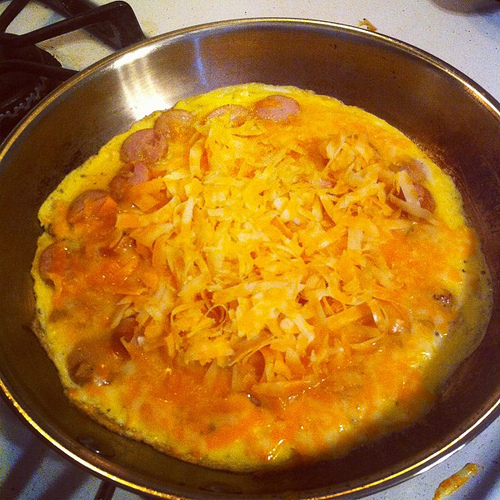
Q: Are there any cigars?
A: No, there are no cigars.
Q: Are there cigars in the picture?
A: No, there are no cigars.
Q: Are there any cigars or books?
A: No, there are no cigars or books.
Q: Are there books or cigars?
A: No, there are no cigars or books.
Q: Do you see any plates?
A: No, there are no plates.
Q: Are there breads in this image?
A: No, there are no breads.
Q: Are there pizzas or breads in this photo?
A: No, there are no breads or pizzas.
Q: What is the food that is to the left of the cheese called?
A: The food is a sausage.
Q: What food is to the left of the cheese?
A: The food is a sausage.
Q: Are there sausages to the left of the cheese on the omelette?
A: Yes, there is a sausage to the left of the cheese.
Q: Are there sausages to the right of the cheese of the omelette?
A: No, the sausage is to the left of the cheese.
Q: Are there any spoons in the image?
A: No, there are no spoons.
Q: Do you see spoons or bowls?
A: No, there are no spoons or bowls.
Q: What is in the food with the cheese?
A: The sausage is in the omelette.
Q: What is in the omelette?
A: The sausage is in the omelette.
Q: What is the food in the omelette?
A: The food is a sausage.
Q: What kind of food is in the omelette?
A: The food is a sausage.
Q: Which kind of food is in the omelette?
A: The food is a sausage.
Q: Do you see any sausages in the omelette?
A: Yes, there is a sausage in the omelette.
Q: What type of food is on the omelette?
A: The food is a sausage.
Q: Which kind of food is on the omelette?
A: The food is a sausage.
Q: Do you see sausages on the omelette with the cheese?
A: Yes, there is a sausage on the omelette.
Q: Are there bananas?
A: No, there are no bananas.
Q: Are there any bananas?
A: No, there are no bananas.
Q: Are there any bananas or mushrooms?
A: No, there are no bananas or mushrooms.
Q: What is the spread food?
A: The food is omelette.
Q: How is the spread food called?
A: The food is omelette.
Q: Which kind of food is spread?
A: The food is omelette.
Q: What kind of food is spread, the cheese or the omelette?
A: The omelette is spread.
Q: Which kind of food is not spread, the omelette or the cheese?
A: The cheese is not spread.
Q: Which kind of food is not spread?
A: The food is cheese.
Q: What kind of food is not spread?
A: The food is cheese.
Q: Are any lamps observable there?
A: No, there are no lamps.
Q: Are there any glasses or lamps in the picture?
A: No, there are no lamps or glasses.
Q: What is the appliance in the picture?
A: The appliance is a stove.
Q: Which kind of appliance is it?
A: The appliance is a stove.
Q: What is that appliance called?
A: This is a stove.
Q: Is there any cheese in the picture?
A: Yes, there is cheese.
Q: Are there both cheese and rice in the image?
A: No, there is cheese but no rice.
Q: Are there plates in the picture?
A: No, there are no plates.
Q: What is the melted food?
A: The food is cheese.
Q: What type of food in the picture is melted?
A: The food is cheese.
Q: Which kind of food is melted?
A: The food is cheese.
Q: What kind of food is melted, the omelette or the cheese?
A: The cheese is melted.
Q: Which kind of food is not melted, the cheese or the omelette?
A: The omelette is not melted.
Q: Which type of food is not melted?
A: The food is omelette.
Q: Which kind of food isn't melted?
A: The food is omelette.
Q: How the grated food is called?
A: The food is cheese.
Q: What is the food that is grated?
A: The food is cheese.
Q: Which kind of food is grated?
A: The food is cheese.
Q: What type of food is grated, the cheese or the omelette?
A: The cheese is grated.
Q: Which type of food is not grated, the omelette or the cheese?
A: The omelette is not grated.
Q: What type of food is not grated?
A: The food is omelette.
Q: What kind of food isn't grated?
A: The food is omelette.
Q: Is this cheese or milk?
A: This is cheese.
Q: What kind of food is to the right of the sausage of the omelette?
A: The food is cheese.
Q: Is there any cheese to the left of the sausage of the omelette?
A: No, the cheese is to the right of the sausage.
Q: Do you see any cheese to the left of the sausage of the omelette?
A: No, the cheese is to the right of the sausage.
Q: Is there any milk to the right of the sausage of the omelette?
A: No, there is cheese to the right of the sausage.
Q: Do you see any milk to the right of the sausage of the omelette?
A: No, there is cheese to the right of the sausage.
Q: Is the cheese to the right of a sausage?
A: Yes, the cheese is to the right of a sausage.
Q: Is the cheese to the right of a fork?
A: No, the cheese is to the right of a sausage.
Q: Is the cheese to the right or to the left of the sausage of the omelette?
A: The cheese is to the right of the sausage.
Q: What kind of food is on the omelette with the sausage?
A: The food is cheese.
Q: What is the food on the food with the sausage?
A: The food is cheese.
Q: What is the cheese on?
A: The cheese is on the omelette.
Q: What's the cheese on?
A: The cheese is on the omelette.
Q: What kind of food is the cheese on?
A: The cheese is on the omelette.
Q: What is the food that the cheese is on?
A: The food is omelette.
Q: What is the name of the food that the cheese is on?
A: The food is omelette.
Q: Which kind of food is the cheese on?
A: The cheese is on the omelette.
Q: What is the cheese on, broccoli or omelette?
A: The cheese is on omelette.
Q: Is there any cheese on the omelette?
A: Yes, there is cheese on the omelette.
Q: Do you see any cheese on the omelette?
A: Yes, there is cheese on the omelette.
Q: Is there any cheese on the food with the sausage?
A: Yes, there is cheese on the omelette.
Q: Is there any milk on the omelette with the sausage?
A: No, there is cheese on the omelette.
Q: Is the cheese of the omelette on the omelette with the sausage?
A: Yes, the cheese is on the omelette.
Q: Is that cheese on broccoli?
A: No, the cheese is on the omelette.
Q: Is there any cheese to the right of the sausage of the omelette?
A: Yes, there is cheese to the right of the sausage.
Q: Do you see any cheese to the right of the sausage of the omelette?
A: Yes, there is cheese to the right of the sausage.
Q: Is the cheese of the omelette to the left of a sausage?
A: No, the cheese is to the right of a sausage.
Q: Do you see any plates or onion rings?
A: No, there are no plates or onion rings.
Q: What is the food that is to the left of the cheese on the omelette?
A: The food is a sausage.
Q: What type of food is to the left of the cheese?
A: The food is a sausage.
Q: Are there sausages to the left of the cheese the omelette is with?
A: Yes, there is a sausage to the left of the cheese.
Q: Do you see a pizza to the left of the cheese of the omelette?
A: No, there is a sausage to the left of the cheese.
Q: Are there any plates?
A: No, there are no plates.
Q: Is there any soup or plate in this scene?
A: No, there are no plates or soup.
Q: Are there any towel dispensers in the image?
A: No, there are no towel dispensers.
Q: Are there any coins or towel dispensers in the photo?
A: No, there are no towel dispensers or coins.